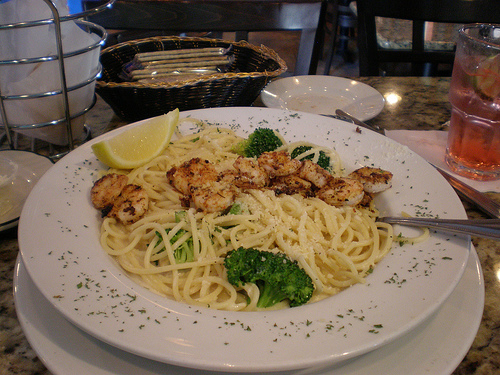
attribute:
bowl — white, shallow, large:
[18, 106, 472, 373]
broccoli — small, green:
[232, 127, 283, 157]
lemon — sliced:
[92, 107, 181, 168]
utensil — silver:
[368, 216, 499, 241]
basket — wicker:
[96, 35, 288, 122]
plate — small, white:
[260, 75, 386, 124]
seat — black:
[355, 0, 499, 77]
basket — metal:
[1, 1, 114, 160]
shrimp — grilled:
[90, 148, 393, 225]